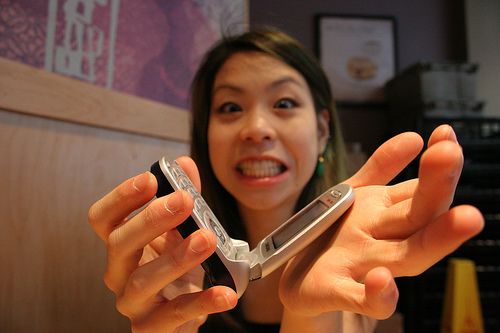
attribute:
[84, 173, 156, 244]
finger — bare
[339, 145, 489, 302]
finger — bare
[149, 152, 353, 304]
phone — silver, grey, flip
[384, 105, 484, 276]
finger — bare